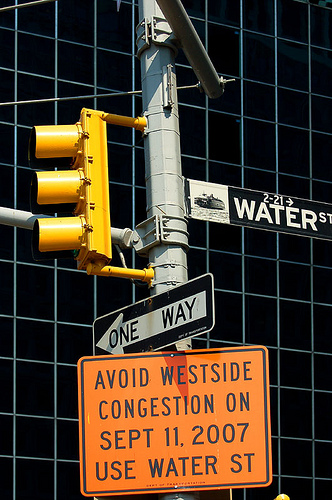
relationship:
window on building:
[59, 270, 92, 324] [13, 22, 308, 495]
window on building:
[14, 412, 61, 465] [2, 2, 328, 497]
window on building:
[276, 36, 310, 94] [2, 2, 328, 497]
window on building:
[235, 285, 284, 354] [2, 2, 328, 497]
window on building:
[14, 360, 55, 416] [2, 2, 328, 497]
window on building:
[239, 114, 276, 171] [2, 2, 328, 497]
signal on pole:
[26, 111, 103, 273] [137, 8, 191, 350]